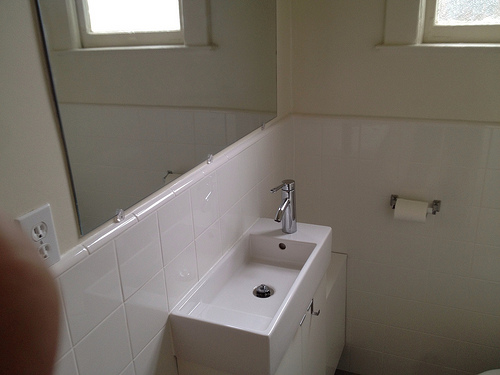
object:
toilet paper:
[393, 197, 429, 223]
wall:
[293, 114, 499, 374]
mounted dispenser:
[389, 194, 441, 216]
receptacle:
[325, 249, 347, 374]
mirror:
[35, 1, 277, 237]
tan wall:
[1, 1, 291, 274]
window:
[433, 1, 500, 26]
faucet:
[269, 179, 298, 234]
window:
[85, 0, 179, 38]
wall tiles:
[54, 244, 127, 347]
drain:
[252, 284, 275, 297]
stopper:
[255, 283, 269, 294]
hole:
[277, 241, 286, 249]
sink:
[170, 216, 332, 371]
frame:
[373, 2, 498, 61]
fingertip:
[0, 210, 63, 374]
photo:
[0, 0, 498, 373]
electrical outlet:
[15, 205, 60, 269]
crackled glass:
[433, 0, 500, 27]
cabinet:
[270, 276, 338, 374]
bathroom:
[1, 0, 500, 374]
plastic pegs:
[110, 120, 266, 224]